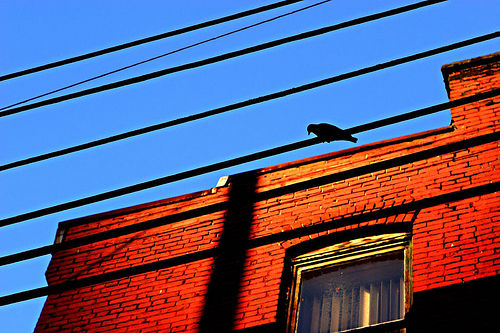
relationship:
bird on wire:
[307, 122, 360, 144] [1, 85, 499, 228]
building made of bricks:
[34, 50, 500, 333] [51, 263, 270, 333]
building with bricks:
[34, 50, 500, 333] [51, 263, 270, 333]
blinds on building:
[299, 275, 403, 332] [34, 50, 500, 333]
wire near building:
[1, 85, 499, 228] [34, 50, 500, 333]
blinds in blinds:
[306, 284, 402, 329] [299, 275, 403, 332]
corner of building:
[58, 212, 109, 250] [34, 50, 500, 333]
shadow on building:
[196, 171, 499, 333] [34, 50, 500, 333]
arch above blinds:
[270, 200, 425, 247] [299, 275, 403, 332]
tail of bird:
[350, 137, 357, 144] [307, 122, 360, 144]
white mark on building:
[216, 176, 230, 187] [34, 50, 500, 333]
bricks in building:
[51, 263, 270, 333] [34, 50, 500, 333]